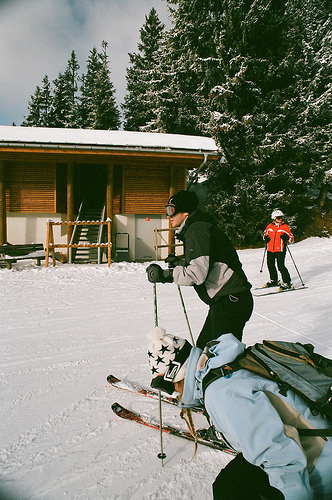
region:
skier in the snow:
[255, 201, 314, 304]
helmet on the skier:
[267, 204, 284, 224]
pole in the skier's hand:
[279, 231, 309, 286]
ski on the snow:
[256, 285, 311, 294]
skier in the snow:
[151, 317, 327, 489]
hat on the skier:
[143, 324, 188, 385]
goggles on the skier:
[147, 368, 176, 391]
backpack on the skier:
[245, 334, 330, 411]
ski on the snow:
[109, 396, 174, 441]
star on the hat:
[157, 343, 170, 354]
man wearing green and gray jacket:
[154, 185, 264, 337]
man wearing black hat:
[131, 188, 245, 353]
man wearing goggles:
[137, 183, 237, 332]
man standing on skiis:
[131, 185, 260, 390]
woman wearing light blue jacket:
[129, 319, 323, 474]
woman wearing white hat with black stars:
[129, 319, 319, 491]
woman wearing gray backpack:
[144, 318, 323, 476]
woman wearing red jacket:
[256, 202, 310, 285]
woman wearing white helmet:
[254, 195, 314, 304]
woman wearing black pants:
[261, 204, 307, 298]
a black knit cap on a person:
[168, 186, 200, 208]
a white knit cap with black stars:
[147, 327, 189, 379]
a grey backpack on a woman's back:
[238, 337, 330, 403]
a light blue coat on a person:
[186, 332, 330, 499]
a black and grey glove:
[146, 263, 174, 282]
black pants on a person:
[188, 288, 254, 347]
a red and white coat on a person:
[263, 221, 294, 249]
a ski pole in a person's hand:
[283, 242, 308, 287]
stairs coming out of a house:
[69, 188, 107, 263]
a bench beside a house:
[0, 240, 46, 268]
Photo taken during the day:
[18, 12, 330, 491]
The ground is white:
[11, 236, 325, 493]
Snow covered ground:
[8, 236, 328, 496]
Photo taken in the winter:
[6, 12, 320, 492]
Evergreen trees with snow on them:
[37, 9, 327, 238]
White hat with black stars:
[145, 329, 200, 384]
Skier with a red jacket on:
[251, 203, 309, 302]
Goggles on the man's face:
[164, 207, 187, 221]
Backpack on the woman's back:
[203, 331, 331, 441]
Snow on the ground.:
[35, 385, 165, 463]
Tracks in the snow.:
[46, 364, 142, 468]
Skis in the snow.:
[65, 349, 194, 489]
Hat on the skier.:
[115, 335, 300, 446]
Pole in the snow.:
[131, 269, 163, 491]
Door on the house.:
[53, 138, 150, 266]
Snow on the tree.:
[197, 77, 275, 167]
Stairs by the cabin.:
[50, 186, 125, 278]